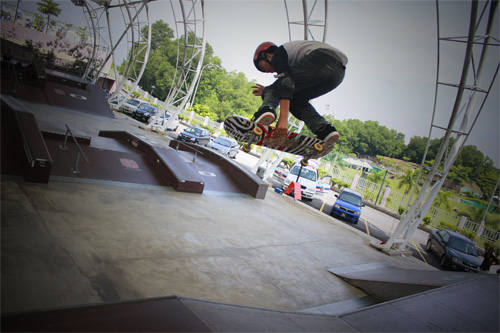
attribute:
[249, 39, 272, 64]
helmet — red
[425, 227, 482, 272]
car — dark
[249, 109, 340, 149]
sneakers — black, white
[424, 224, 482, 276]
car — parked, distant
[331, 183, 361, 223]
car — parked, distant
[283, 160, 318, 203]
car — parked, distant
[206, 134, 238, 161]
car — parked, distant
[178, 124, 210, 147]
car — distant, parked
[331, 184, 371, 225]
car — blue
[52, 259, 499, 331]
ramp — concrete, gray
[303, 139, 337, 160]
tires — yellow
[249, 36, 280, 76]
helmet — red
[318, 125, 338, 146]
shoe — black 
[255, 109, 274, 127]
shoe — white 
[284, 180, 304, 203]
sign — orange 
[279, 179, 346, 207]
car — White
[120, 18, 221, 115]
tree — green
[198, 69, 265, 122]
tree — green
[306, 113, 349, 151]
tree — green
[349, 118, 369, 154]
tree — green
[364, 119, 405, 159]
tree — green